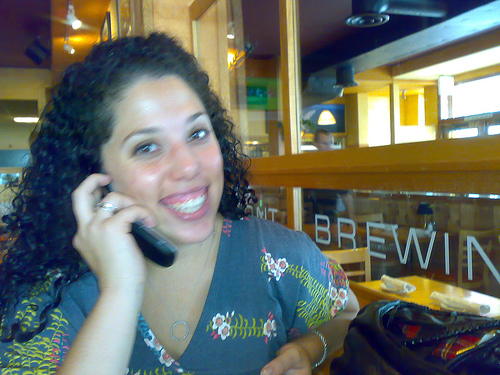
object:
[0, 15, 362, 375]
lady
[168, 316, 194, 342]
charm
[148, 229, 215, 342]
necklace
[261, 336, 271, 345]
daisy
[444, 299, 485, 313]
utensils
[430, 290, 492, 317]
napkin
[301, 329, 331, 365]
bracelet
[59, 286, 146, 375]
arm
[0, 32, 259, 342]
hair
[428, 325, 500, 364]
purse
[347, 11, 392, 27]
vent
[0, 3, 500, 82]
ceiling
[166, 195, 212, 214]
teeth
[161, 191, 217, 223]
lips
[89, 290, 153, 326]
wrist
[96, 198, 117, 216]
rings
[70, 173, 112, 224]
finger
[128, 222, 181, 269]
cell phone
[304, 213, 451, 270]
brewin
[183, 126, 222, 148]
eyes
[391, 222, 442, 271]
letter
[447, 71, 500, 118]
window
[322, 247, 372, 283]
chair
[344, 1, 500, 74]
beam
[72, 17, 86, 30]
light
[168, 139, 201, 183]
nose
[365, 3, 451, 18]
fan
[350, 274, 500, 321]
table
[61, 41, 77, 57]
lights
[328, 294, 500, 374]
bag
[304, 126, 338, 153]
man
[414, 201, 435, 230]
lamp